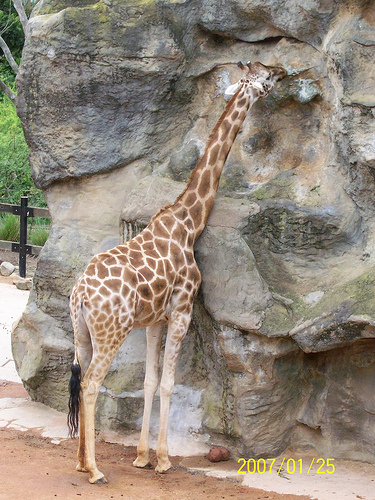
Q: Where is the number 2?
A: The bottom right corner.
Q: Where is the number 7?
A: The bottom right corner.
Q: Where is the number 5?
A: The bottom right corner.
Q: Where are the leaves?
A: On the tree.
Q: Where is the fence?
A: Behind the rock.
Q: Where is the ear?
A: On the giraffe.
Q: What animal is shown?
A: A giraffe.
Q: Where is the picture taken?
A: A zoo.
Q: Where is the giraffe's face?
A: Against the rock.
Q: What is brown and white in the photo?
A: Giraffe.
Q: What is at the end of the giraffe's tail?
A: Black fur.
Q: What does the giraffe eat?
A: Grasses.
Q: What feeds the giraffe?
A: A keeper or worker.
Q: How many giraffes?
A: One.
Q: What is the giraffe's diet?
A: Vegetarian.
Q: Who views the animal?
A: Visitors.